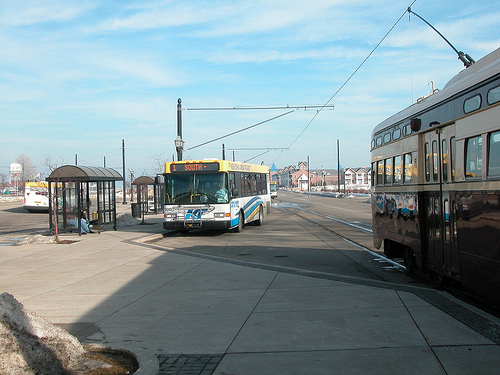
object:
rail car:
[369, 6, 500, 300]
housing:
[269, 160, 371, 190]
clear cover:
[53, 182, 83, 212]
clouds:
[0, 0, 500, 182]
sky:
[0, 0, 497, 186]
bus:
[155, 157, 272, 234]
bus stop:
[44, 164, 124, 234]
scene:
[34, 0, 488, 371]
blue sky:
[0, 0, 498, 187]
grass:
[87, 353, 130, 374]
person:
[62, 204, 91, 235]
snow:
[0, 292, 88, 375]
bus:
[369, 47, 500, 302]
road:
[292, 195, 369, 247]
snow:
[342, 238, 406, 271]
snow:
[271, 200, 307, 210]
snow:
[340, 218, 372, 232]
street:
[0, 187, 497, 375]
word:
[173, 164, 208, 172]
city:
[1, 24, 500, 375]